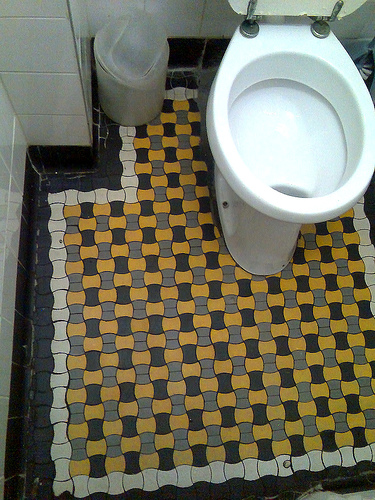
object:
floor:
[21, 66, 374, 498]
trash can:
[84, 6, 168, 130]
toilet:
[0, 0, 374, 499]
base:
[213, 163, 304, 277]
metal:
[310, 21, 330, 41]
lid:
[227, 0, 367, 21]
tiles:
[60, 427, 98, 469]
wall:
[0, 0, 92, 169]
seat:
[211, 19, 374, 217]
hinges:
[238, 0, 261, 40]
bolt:
[220, 198, 227, 210]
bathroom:
[0, 0, 374, 499]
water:
[284, 188, 297, 195]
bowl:
[205, 24, 375, 225]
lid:
[109, 7, 168, 79]